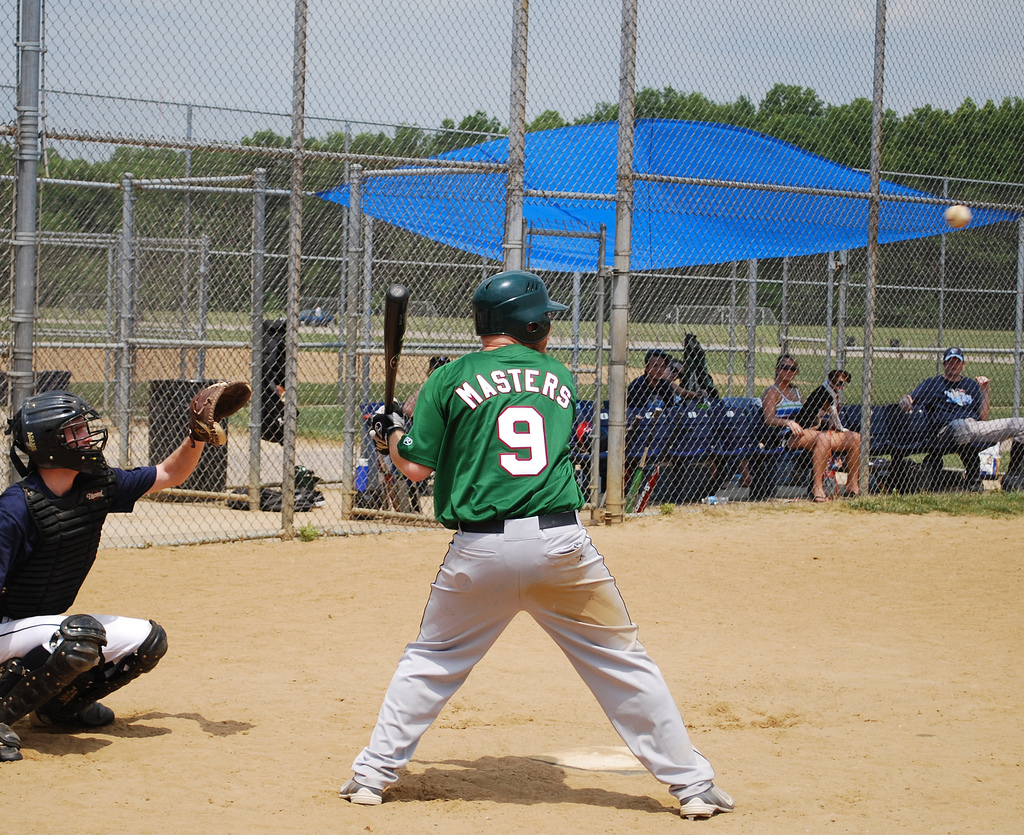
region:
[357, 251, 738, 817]
a person is playing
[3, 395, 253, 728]
a person is playing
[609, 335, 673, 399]
a person is sitting down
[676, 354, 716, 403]
a person is sitting down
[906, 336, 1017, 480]
a person is sitting down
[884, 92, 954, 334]
a tree in the woods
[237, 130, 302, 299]
a tree in the woods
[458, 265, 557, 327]
Batter wearing helmet on head.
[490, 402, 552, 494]
White number 9 on back of shirt.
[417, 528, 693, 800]
Batter wearing white pants.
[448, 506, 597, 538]
Batter wearing black belt.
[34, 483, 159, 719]
Catcher is wearing black padding and leg protection.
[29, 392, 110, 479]
Catcher is wearing black helmet.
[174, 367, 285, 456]
Brown glove on left hand.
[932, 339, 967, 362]
Person wearing baseball cap.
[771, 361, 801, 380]
Sunglasses on woman's face.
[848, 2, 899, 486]
metal pole on the fence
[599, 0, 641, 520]
metal pole on the fence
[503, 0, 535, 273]
metal pole on the fence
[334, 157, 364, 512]
metal pole on the fence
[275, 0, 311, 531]
metal pole on the fence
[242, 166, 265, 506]
metal pole on the fence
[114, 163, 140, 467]
metal pole on the fence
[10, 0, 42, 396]
metal pole on the fence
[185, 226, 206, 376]
metal pole on the fence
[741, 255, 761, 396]
metal pole on the fence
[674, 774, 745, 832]
shoes are black and white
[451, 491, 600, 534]
belt of batter is black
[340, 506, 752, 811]
pants of batter are white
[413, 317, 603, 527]
shirt of batter is green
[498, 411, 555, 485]
shirt has white number on it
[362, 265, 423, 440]
bat is black in color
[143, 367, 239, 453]
catchers glove is brown in color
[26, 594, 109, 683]
catcher is wearing kneepads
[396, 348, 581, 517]
baseball player wearing a green jersey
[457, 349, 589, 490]
Masters 9 on the back of a green tshirt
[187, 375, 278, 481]
brown catchers glove on mans hand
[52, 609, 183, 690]
knee pads on the man's knees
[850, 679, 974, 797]
tan sand on the ground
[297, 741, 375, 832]
gray sneakers on the batter's left foot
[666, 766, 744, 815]
gray sneaker on the right foot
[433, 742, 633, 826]
shadow of the batter on the ground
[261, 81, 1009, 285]
blue tarp over the field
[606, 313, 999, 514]
people watching the baseball game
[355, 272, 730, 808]
baseball player holding a bat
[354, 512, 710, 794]
white pants with a black belt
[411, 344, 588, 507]
green jersey with a player's name and number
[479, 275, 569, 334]
the baseball helmet is green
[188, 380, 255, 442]
the leather glove is brown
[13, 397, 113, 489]
the baseball catcher wearing a helmet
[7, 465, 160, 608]
the teeshirt is blue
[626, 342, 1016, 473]
people sitting in chairs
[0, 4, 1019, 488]
grey posts with chain link fencing attached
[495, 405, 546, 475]
number on shirt of batter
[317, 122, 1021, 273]
blue tarp on top of spectators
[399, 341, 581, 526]
batter wearing green shirt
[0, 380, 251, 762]
catcher squatting behind batter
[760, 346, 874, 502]
person watching baseball game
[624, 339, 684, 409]
person watching baseball game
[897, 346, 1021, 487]
person watching baseball game